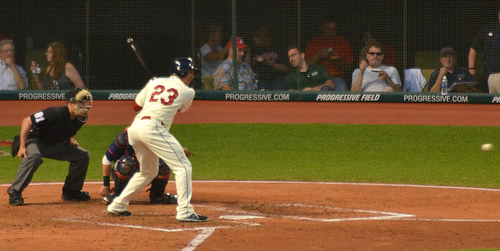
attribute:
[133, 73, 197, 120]
shirt — white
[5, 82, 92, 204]
man — bent down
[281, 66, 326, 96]
shirt — green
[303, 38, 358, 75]
shirt — orange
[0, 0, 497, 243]
field — green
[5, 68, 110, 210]
uniform — black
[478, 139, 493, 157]
ball — base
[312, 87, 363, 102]
word — white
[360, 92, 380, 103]
word — white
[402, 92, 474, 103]
word — white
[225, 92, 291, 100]
word — white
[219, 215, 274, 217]
surface — white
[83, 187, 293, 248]
box — batter's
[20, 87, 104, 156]
shirt — black